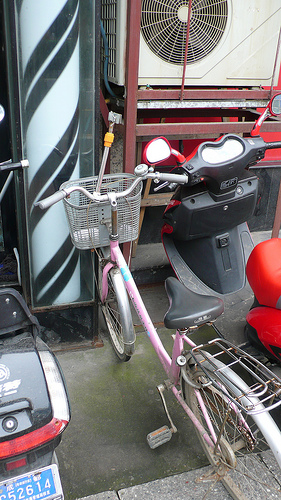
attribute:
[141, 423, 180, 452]
pedal — gray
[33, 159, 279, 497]
bicycle — girls, parked, pink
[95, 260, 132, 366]
wheel — part 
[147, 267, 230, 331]
seat — black, plastic, red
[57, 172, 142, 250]
basket — gray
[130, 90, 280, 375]
scooter — parked, red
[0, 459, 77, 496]
plate — blue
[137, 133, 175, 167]
mirror — red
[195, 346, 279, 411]
fender — silver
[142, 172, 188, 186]
handle — gray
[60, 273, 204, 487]
floor — gray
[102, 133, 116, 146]
tube — yellow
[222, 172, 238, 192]
logo — blue